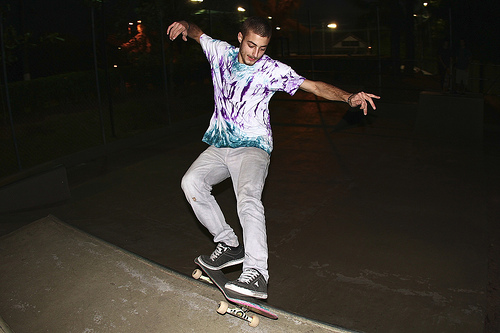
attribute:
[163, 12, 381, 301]
man — skateboarder, looking down, skateboarding, rollerskating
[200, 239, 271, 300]
sneakers — black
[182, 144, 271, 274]
jeans — faded, gray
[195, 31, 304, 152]
shirt — tie dyed, multi-colored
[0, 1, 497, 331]
picture — taken at night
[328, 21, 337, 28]
light — in the distance, artificial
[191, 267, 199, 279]
wheel — yellow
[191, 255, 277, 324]
skateboard — red, black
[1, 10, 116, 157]
fence — around park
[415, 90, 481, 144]
ramp — for skateboarding